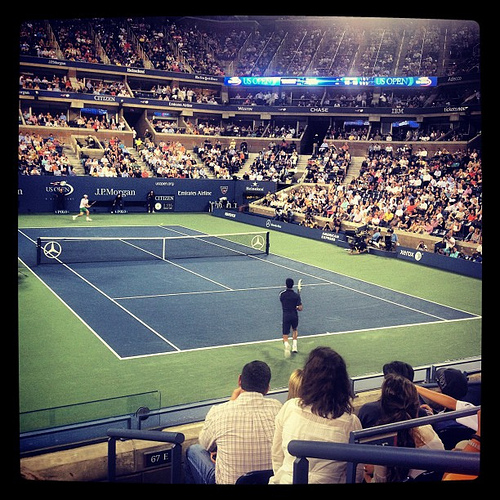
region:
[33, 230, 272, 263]
tennis net on tennis court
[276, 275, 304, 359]
man on tennis court holding racket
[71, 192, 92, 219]
player on court playing tennis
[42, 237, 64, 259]
white logo on tennis net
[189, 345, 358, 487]
spectators watching tennis match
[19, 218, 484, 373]
tennis court in arena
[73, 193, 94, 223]
tennis player wearing white shirt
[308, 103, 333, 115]
white logo on arena rafter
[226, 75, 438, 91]
electronic light sign on rafters in arena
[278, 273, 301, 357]
tennis player wearing black shirt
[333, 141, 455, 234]
lot of people sitting in the stadium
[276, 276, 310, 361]
a player is getting ready to play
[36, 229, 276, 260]
net and metal post of the window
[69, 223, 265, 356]
a place marked with white color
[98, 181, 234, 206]
advertisement banner near the temple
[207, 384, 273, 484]
a person wearing white color checked t-shirt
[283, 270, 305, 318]
a man holding bat on his bed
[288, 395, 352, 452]
a lady wearing white color t-shirt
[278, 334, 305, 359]
a person wearing white color socks and shoe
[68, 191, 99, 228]
a person is ready to play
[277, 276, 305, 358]
a man playing tennis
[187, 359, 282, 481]
a male tennis spectator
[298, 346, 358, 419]
back of a woman's head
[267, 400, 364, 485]
a woman's white blouse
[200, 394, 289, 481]
a man's plaid shirt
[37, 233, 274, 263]
a net on a tennis court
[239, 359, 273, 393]
back of a man's head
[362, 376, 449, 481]
a woman wearing a pony tail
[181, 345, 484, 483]
spectators at a tennis match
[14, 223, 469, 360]
a tennis court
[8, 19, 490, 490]
professional tennis match in progress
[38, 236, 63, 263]
mercedes benz sponser logo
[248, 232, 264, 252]
mercedes benz sponsor logo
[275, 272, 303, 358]
tennis player dressed in blue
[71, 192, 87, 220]
tennis player dressed in white and green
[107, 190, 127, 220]
ball boy dressed in navy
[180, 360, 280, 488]
spectator dressed in plaid shirt and blue jeans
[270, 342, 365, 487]
female spectator dress in white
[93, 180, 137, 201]
j.p.morgan in white on blue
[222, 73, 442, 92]
tennis match scoreboard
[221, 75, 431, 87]
indoor arena scoreboard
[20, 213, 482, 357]
tennis court set up inside arena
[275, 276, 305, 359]
tennis player in dark shorts and shirt and white socks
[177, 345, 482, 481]
spectators in the stands at tennis match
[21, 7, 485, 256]
indoor arena seating with spectators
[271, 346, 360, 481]
woman with dark hair wearing white blouse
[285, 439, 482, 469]
metal top rail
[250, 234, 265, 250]
tennis match sponsor logo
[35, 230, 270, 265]
tennis net with two Mercedes logos